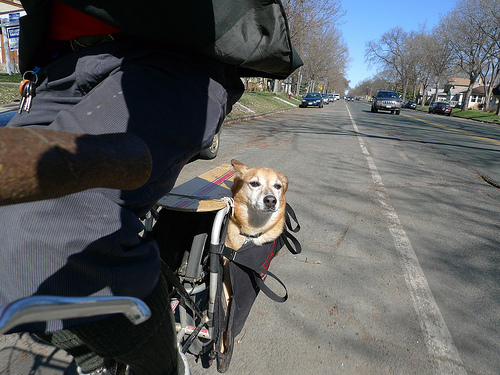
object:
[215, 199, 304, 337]
dog carrier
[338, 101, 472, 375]
line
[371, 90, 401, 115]
car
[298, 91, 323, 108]
car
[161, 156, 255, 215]
board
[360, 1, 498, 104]
tree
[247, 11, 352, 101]
tree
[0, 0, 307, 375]
man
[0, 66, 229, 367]
pants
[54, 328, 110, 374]
socks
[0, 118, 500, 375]
road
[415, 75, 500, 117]
buildings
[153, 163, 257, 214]
skateboard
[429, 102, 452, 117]
car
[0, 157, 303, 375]
bike rack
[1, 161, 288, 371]
bicycle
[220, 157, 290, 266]
dog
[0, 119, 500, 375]
street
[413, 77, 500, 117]
row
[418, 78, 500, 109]
house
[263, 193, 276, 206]
nose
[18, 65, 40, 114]
keys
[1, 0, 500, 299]
neighborhood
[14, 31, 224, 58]
belt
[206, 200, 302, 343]
bag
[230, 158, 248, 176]
ear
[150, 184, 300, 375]
carrier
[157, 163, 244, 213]
stripe